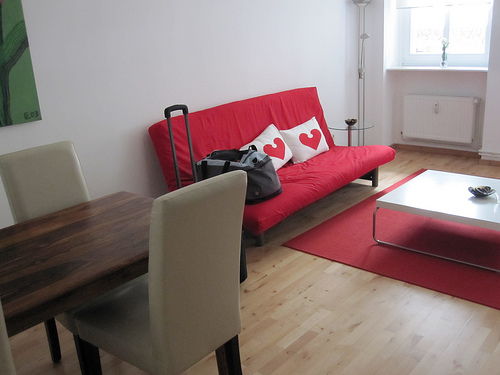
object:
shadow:
[263, 182, 381, 243]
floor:
[0, 139, 499, 374]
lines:
[257, 329, 312, 372]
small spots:
[241, 287, 249, 294]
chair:
[72, 170, 247, 374]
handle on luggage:
[164, 102, 199, 186]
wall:
[0, 0, 356, 234]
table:
[0, 189, 231, 321]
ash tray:
[468, 185, 499, 199]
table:
[373, 168, 498, 248]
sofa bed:
[148, 85, 396, 247]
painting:
[0, 0, 43, 129]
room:
[0, 0, 499, 375]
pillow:
[279, 115, 329, 163]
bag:
[197, 148, 282, 203]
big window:
[396, 0, 489, 67]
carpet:
[281, 168, 499, 311]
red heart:
[264, 138, 289, 161]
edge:
[47, 287, 112, 300]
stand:
[366, 206, 499, 275]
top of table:
[1, 190, 160, 314]